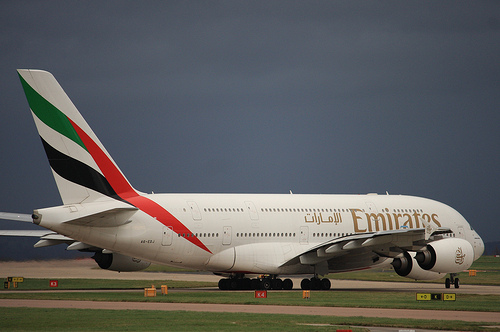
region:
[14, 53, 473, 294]
large plane on runway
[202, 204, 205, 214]
small window on side of plane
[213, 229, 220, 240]
small window on side of plane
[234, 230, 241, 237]
small window on side of plane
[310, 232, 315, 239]
small window on side of plane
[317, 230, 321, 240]
small window on side of plane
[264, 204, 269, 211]
small window on side of plane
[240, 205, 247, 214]
small window on side of plane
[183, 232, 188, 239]
small window on side of plane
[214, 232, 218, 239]
small window on side of plane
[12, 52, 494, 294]
the large airplane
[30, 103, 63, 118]
the green on the plane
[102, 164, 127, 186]
the red on the plane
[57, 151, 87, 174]
the black on the plane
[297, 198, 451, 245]
the words on the plane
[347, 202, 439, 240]
the word Emirates on the plane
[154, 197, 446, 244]
the windows on the side of the plane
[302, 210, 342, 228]
the foreign words on the side of the plane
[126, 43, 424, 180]
the dark gray sky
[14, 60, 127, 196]
the tail of the plane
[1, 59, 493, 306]
a white plane on an airport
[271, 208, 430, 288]
right wing of plane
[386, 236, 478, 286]
two engines in front of wing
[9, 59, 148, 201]
vertical stabilizer on plane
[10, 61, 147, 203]
stabilizer has green, black and red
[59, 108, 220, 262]
a red stripe on plane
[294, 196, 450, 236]
brown letters on plane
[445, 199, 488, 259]
windows of cockpit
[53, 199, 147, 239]
vertical stabilizer of plane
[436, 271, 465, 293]
wheel in front of plane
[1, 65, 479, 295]
commercial airplane on runway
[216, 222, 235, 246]
side door on airplane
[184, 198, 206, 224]
side door on airplane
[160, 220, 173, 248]
side door on airplane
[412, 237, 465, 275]
side engine on plane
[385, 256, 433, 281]
side engine on plane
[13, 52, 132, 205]
tail on back of plane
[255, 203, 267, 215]
small window on plane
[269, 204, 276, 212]
small window on plane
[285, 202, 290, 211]
small window on plane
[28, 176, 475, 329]
Jet plane parked on runway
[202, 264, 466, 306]
Plane with landing gear down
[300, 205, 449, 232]
Gold lettering on plane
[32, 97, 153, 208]
Red, green, black and white tail on plane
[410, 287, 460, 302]
Yellow and black sign near runway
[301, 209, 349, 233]
Arabic writing on plane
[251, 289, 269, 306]
Red and white sign on ground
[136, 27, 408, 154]
Gray, cloudy sky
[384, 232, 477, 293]
Two black, white and gold engines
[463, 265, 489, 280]
Orange safety marker on ground